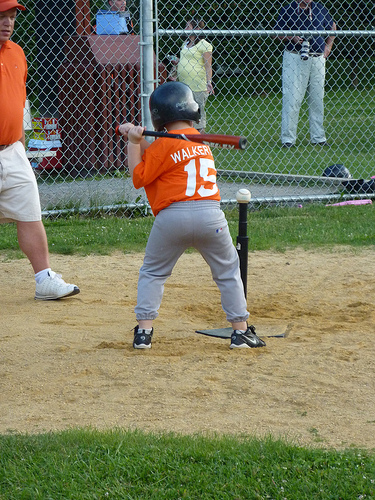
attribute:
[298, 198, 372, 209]
bat — pink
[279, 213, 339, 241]
grass — green, long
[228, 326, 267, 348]
shoes — black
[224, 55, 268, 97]
gate — silver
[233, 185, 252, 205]
baseball — small, white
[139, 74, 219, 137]
helmet — black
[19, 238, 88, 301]
shoes — white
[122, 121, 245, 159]
bat — baseball bat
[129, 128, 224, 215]
shirt — orange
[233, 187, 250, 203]
baseball — black 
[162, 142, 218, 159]
word — white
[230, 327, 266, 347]
shoe — black, white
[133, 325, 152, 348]
shoe — black, white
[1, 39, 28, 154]
shirt — orange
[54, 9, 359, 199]
link fence — chain link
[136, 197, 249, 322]
pants — gray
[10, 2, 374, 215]
chainlink fence — chain link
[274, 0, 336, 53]
shirt — blue